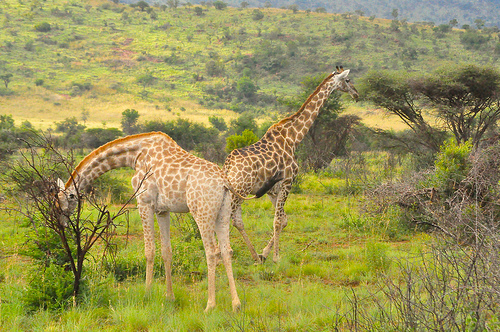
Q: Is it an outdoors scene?
A: Yes, it is outdoors.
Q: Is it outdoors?
A: Yes, it is outdoors.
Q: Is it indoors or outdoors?
A: It is outdoors.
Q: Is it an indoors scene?
A: No, it is outdoors.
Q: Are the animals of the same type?
A: Yes, all the animals are giraffes.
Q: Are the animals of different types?
A: No, all the animals are giraffes.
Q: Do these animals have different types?
A: No, all the animals are giraffes.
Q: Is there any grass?
A: Yes, there is grass.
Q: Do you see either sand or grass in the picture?
A: Yes, there is grass.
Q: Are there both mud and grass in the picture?
A: No, there is grass but no mud.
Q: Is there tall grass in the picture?
A: Yes, there is tall grass.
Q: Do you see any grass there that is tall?
A: Yes, there is grass that is tall.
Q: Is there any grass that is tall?
A: Yes, there is grass that is tall.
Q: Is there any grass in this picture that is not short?
A: Yes, there is tall grass.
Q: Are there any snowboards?
A: No, there are no snowboards.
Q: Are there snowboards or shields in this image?
A: No, there are no snowboards or shields.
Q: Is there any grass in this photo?
A: Yes, there is grass.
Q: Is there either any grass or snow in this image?
A: Yes, there is grass.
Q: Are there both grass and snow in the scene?
A: No, there is grass but no snow.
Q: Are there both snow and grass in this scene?
A: No, there is grass but no snow.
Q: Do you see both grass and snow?
A: No, there is grass but no snow.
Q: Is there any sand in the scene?
A: No, there is no sand.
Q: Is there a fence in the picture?
A: No, there are no fences.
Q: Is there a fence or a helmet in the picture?
A: No, there are no fences or helmets.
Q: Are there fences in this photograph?
A: No, there are no fences.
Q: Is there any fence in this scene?
A: No, there are no fences.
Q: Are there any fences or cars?
A: No, there are no fences or cars.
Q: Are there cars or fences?
A: No, there are no fences or cars.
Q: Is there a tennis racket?
A: No, there are no rackets.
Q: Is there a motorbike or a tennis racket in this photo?
A: No, there are no rackets or motorcycles.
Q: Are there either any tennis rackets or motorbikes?
A: No, there are no tennis rackets or motorbikes.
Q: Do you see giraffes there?
A: Yes, there is a giraffe.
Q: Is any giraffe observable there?
A: Yes, there is a giraffe.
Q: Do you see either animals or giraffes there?
A: Yes, there is a giraffe.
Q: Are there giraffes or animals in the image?
A: Yes, there is a giraffe.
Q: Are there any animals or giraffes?
A: Yes, there is a giraffe.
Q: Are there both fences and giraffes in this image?
A: No, there is a giraffe but no fences.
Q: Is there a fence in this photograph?
A: No, there are no fences.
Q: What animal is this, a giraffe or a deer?
A: This is a giraffe.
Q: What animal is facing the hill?
A: The giraffe is facing the hill.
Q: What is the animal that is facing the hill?
A: The animal is a giraffe.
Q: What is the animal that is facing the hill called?
A: The animal is a giraffe.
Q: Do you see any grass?
A: Yes, there is grass.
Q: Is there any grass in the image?
A: Yes, there is grass.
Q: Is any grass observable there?
A: Yes, there is grass.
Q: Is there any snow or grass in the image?
A: Yes, there is grass.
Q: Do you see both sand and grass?
A: No, there is grass but no sand.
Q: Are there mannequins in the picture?
A: No, there are no mannequins.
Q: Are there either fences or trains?
A: No, there are no fences or trains.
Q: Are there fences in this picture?
A: No, there are no fences.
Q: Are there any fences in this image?
A: No, there are no fences.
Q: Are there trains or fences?
A: No, there are no fences or trains.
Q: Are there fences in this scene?
A: No, there are no fences.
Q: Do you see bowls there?
A: No, there are no bowls.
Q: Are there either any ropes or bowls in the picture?
A: No, there are no bowls or ropes.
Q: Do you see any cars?
A: No, there are no cars.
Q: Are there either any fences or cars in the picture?
A: No, there are no cars or fences.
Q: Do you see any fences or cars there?
A: No, there are no cars or fences.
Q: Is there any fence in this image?
A: No, there are no fences.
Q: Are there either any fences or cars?
A: No, there are no fences or cars.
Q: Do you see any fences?
A: No, there are no fences.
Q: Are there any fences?
A: No, there are no fences.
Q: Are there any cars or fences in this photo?
A: No, there are no fences or cars.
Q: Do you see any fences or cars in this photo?
A: No, there are no fences or cars.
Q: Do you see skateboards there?
A: No, there are no skateboards.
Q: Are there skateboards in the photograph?
A: No, there are no skateboards.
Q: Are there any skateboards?
A: No, there are no skateboards.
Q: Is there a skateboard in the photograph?
A: No, there are no skateboards.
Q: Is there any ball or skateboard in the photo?
A: No, there are no skateboards or balls.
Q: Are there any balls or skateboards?
A: No, there are no skateboards or balls.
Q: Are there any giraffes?
A: Yes, there is a giraffe.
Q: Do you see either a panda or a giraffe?
A: Yes, there is a giraffe.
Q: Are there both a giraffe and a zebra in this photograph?
A: No, there is a giraffe but no zebras.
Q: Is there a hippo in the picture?
A: No, there are no hippos.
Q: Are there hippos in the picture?
A: No, there are no hippos.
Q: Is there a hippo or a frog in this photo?
A: No, there are no hippos or frogs.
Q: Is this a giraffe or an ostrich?
A: This is a giraffe.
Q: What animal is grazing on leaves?
A: The giraffe is grazing on leaves.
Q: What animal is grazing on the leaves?
A: The giraffe is grazing on leaves.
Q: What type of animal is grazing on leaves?
A: The animal is a giraffe.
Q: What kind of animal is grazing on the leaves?
A: The animal is a giraffe.